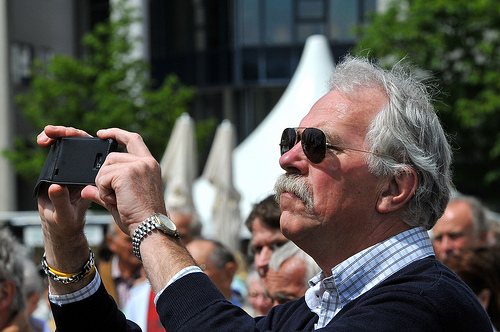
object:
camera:
[32, 134, 115, 195]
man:
[33, 55, 499, 332]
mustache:
[273, 174, 316, 211]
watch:
[129, 213, 181, 259]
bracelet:
[41, 246, 97, 285]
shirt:
[47, 226, 500, 332]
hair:
[325, 53, 455, 231]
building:
[146, 0, 414, 140]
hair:
[244, 193, 283, 231]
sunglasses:
[280, 126, 404, 167]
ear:
[376, 165, 418, 213]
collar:
[305, 224, 439, 303]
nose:
[278, 141, 309, 175]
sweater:
[46, 258, 498, 332]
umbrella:
[160, 113, 196, 212]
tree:
[354, 0, 500, 211]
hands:
[79, 126, 166, 231]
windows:
[259, 0, 295, 45]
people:
[431, 194, 491, 272]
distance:
[0, 0, 498, 261]